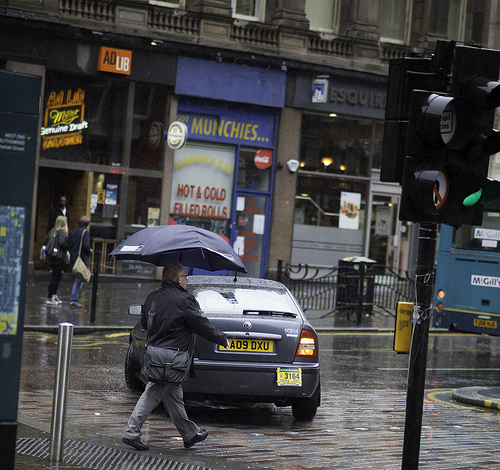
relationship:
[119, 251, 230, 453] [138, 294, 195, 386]
man carrying satchel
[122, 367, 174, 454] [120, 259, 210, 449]
leg part of man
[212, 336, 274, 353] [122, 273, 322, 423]
license plate on car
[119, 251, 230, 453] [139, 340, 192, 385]
man has bag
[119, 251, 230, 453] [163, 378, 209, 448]
man has leg